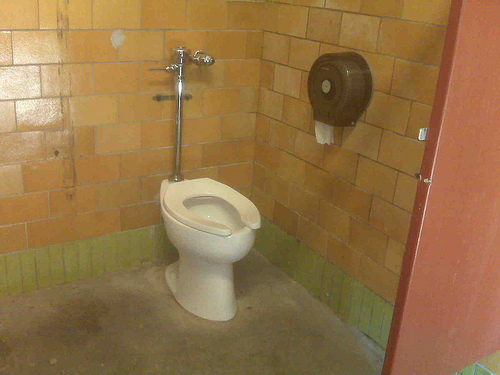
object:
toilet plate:
[163, 177, 261, 237]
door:
[382, 0, 500, 375]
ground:
[265, 147, 331, 215]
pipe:
[147, 46, 215, 183]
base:
[164, 262, 238, 322]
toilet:
[160, 177, 262, 322]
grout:
[0, 0, 458, 351]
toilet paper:
[307, 49, 373, 146]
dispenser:
[306, 51, 372, 128]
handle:
[147, 62, 176, 73]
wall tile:
[91, 60, 142, 96]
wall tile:
[64, 29, 119, 64]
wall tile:
[96, 120, 143, 157]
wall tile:
[113, 29, 166, 62]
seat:
[163, 176, 261, 236]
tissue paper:
[315, 120, 335, 145]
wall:
[1, 4, 266, 297]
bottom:
[252, 217, 398, 355]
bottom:
[0, 223, 174, 301]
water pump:
[147, 46, 214, 183]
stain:
[54, 297, 107, 336]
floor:
[0, 249, 386, 374]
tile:
[1, 2, 459, 351]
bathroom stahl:
[382, 0, 500, 375]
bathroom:
[0, 1, 386, 372]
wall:
[255, 0, 453, 350]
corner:
[230, 0, 282, 198]